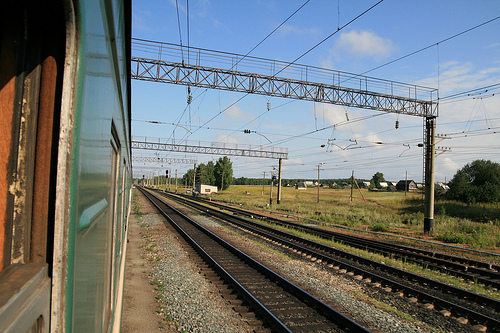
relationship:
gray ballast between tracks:
[158, 247, 353, 332] [133, 183, 498, 331]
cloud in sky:
[126, 2, 497, 180] [132, 2, 499, 184]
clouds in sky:
[226, 103, 252, 123] [132, 2, 499, 184]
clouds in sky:
[331, 132, 383, 154] [132, 2, 499, 184]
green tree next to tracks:
[213, 155, 234, 191] [133, 183, 498, 331]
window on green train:
[103, 118, 119, 328] [1, 0, 129, 330]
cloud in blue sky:
[126, 2, 497, 180] [113, 0, 500, 177]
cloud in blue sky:
[441, 154, 465, 172] [113, 0, 500, 177]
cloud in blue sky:
[126, 2, 497, 180] [132, 0, 498, 181]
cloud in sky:
[126, 2, 497, 180] [134, 6, 479, 178]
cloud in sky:
[126, 2, 497, 180] [418, 22, 480, 39]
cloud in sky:
[126, 2, 497, 180] [130, 0, 470, 157]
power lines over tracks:
[142, 4, 498, 162] [133, 183, 498, 331]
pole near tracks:
[421, 113, 439, 235] [139, 176, 497, 320]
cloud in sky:
[126, 2, 497, 180] [206, 11, 254, 41]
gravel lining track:
[136, 226, 191, 281] [135, 185, 368, 333]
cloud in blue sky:
[126, 2, 497, 180] [132, 0, 490, 98]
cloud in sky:
[126, 2, 497, 180] [128, 7, 476, 242]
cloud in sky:
[328, 35, 394, 60] [132, 2, 499, 184]